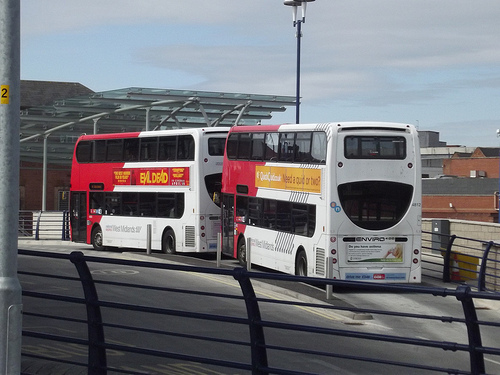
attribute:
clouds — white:
[123, 32, 498, 89]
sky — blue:
[22, 0, 498, 87]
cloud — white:
[144, 36, 498, 109]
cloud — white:
[2, 0, 468, 46]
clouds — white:
[204, 29, 354, 99]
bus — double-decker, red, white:
[56, 115, 429, 293]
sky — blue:
[20, 0, 497, 145]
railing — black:
[62, 265, 454, 368]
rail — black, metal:
[21, 246, 499, 373]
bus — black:
[212, 113, 442, 315]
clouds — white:
[318, 12, 495, 99]